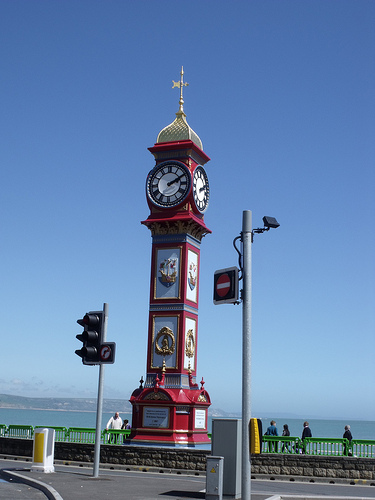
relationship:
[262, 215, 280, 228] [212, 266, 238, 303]
solar panel for sign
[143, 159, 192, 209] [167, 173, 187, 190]
clock says 2:10 pm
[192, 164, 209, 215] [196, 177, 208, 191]
clock says 2:10 pm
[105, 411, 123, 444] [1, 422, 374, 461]
man touching a fence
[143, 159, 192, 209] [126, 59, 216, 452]
clock on tower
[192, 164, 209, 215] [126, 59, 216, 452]
clock on tower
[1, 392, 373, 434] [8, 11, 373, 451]
mountain on horizon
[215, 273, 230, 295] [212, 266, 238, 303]
circle on sign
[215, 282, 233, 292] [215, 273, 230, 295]
line on circle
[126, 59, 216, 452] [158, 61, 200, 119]
tower has tool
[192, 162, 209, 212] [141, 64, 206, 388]
clock on side of tower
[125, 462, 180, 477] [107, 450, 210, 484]
curb on side of sidewalk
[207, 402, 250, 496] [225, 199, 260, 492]
boxes by pole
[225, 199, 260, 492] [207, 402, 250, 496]
pole with boxes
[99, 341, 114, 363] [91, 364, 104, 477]
traffic signal on post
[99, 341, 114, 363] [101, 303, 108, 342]
traffic signal on post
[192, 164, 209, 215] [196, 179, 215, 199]
clock indicating 2:10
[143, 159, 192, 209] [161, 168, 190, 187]
clock indicating 2:10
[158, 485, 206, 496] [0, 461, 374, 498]
shadow on ground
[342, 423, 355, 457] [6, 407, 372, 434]
people near water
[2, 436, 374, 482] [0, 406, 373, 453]
wall near water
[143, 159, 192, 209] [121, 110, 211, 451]
clock on tower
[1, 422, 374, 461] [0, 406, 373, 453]
fence near water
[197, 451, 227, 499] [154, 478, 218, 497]
box casts shadow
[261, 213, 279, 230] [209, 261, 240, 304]
rectangular box attached to sign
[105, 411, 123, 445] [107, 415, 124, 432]
man wears sweater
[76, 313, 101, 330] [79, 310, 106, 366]
light on signal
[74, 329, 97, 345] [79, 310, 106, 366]
light on signal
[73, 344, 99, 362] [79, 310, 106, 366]
light on signal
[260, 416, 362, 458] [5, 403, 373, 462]
people near water